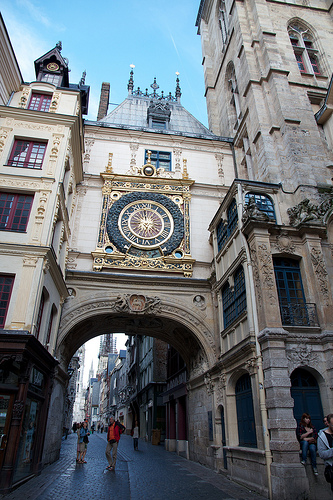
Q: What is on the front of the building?
A: A clock.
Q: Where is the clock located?
A: On a building.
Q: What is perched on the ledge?
A: A gargoyle.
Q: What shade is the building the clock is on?
A: Off white.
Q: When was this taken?
A: Daytime.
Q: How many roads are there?
A: 1.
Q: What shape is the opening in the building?
A: Arch.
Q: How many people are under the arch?
A: 2.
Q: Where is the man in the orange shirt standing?
A: Under the arch.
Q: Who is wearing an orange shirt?
A: Man under the arch.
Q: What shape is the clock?
A: Round.